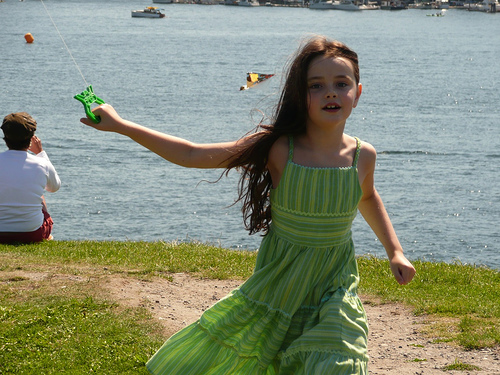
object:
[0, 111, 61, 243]
person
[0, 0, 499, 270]
lake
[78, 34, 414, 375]
girl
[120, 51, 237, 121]
water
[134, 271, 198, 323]
dirt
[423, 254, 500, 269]
sea edge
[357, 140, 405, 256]
arm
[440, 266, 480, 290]
grass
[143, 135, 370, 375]
dress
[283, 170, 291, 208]
yellow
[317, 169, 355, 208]
stripe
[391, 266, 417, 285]
finger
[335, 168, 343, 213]
yellow stripe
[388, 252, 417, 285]
hand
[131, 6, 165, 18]
boat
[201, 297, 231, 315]
edge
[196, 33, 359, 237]
hair